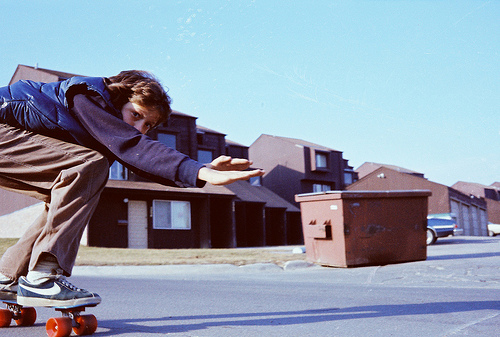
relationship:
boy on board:
[0, 65, 265, 311] [7, 265, 152, 331]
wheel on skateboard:
[46, 314, 73, 335] [1, 285, 106, 335]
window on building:
[147, 195, 194, 227] [5, 65, 297, 242]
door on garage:
[451, 195, 465, 229] [442, 191, 485, 235]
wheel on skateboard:
[16, 303, 37, 327] [0, 287, 100, 334]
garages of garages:
[344, 165, 489, 235] [450, 198, 460, 233]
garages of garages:
[344, 165, 489, 235] [462, 196, 470, 233]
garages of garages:
[344, 165, 489, 235] [471, 197, 479, 237]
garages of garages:
[344, 165, 489, 235] [479, 204, 488, 236]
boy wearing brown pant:
[0, 65, 265, 311] [0, 116, 133, 314]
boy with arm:
[0, 65, 265, 311] [73, 92, 264, 184]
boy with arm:
[0, 65, 265, 311] [112, 155, 254, 185]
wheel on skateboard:
[16, 303, 37, 327] [0, 295, 100, 335]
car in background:
[407, 189, 461, 287] [3, 47, 483, 252]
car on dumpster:
[425, 213, 459, 248] [294, 185, 431, 261]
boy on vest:
[0, 65, 265, 311] [0, 66, 112, 131]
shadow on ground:
[100, 292, 496, 334] [0, 267, 498, 329]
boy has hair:
[0, 65, 265, 311] [104, 65, 172, 110]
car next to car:
[425, 213, 459, 248] [427, 212, 464, 234]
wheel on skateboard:
[46, 314, 73, 335] [1, 288, 98, 306]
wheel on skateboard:
[71, 313, 96, 332] [1, 288, 98, 306]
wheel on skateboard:
[16, 303, 37, 327] [1, 288, 98, 306]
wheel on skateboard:
[1, 309, 11, 324] [1, 288, 98, 306]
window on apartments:
[315, 155, 329, 171] [245, 133, 357, 208]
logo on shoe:
[13, 281, 66, 295] [6, 276, 105, 310]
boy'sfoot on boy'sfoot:
[15, 269, 104, 309] [0, 245, 97, 312]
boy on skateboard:
[0, 65, 265, 311] [0, 267, 110, 334]